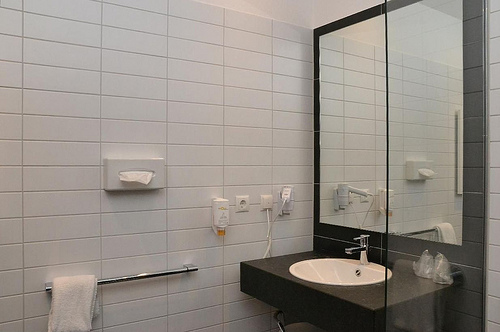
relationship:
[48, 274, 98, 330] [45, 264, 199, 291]
towel hanging on a rack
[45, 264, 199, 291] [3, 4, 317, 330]
rack affixed to wall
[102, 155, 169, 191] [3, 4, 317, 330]
box attached to wall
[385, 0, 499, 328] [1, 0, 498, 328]
wall in a bathroom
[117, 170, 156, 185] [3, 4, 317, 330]
napkin hanging from wall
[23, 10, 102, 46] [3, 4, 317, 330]
tile on wall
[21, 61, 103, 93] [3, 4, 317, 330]
tile on wall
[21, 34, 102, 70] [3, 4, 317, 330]
tile on wall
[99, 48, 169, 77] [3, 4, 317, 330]
tile on wall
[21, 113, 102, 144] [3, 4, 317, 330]
tile on wall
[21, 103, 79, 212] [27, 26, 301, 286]
tile on wall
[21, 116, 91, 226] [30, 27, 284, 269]
tile on wall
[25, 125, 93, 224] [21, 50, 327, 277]
tile on wall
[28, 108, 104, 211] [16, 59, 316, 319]
tile on wall